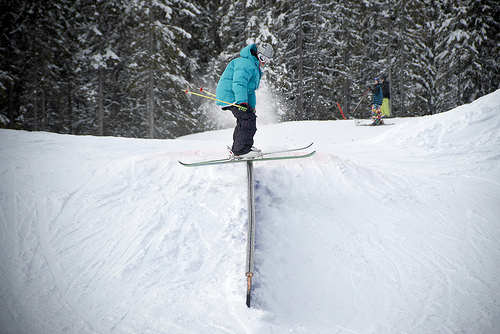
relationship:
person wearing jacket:
[210, 35, 265, 155] [205, 46, 261, 107]